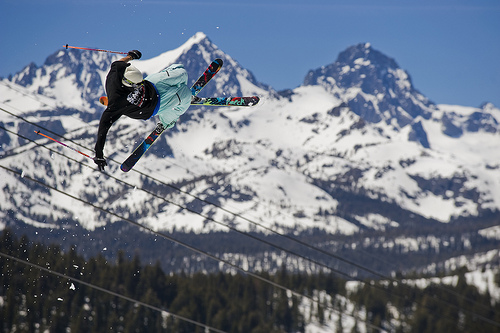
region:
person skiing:
[29, 28, 286, 188]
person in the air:
[13, 26, 291, 184]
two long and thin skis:
[116, 63, 265, 171]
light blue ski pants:
[149, 64, 198, 136]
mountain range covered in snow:
[1, 26, 499, 275]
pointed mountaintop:
[181, 22, 211, 52]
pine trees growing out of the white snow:
[1, 223, 496, 329]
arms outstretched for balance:
[27, 32, 144, 180]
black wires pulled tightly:
[0, 102, 496, 329]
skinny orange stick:
[28, 123, 105, 169]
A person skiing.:
[21, 35, 268, 215]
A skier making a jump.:
[23, 27, 274, 194]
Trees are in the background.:
[17, 242, 306, 330]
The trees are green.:
[35, 265, 259, 332]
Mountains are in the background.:
[281, 25, 477, 193]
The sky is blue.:
[427, 9, 494, 71]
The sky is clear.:
[419, 8, 497, 77]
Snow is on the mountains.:
[288, 20, 497, 187]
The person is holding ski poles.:
[20, 20, 277, 204]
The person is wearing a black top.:
[22, 26, 259, 206]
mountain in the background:
[80, 71, 340, 328]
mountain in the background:
[149, 50, 438, 275]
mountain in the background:
[111, 35, 381, 210]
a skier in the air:
[50, 21, 287, 192]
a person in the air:
[34, 6, 344, 201]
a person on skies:
[22, 17, 322, 228]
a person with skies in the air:
[59, 6, 348, 238]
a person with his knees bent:
[47, 14, 285, 155]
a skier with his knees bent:
[43, 24, 254, 179]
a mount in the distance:
[37, 7, 475, 309]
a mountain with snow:
[14, 27, 481, 327]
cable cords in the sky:
[10, 63, 331, 331]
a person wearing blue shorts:
[51, 13, 362, 188]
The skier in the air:
[90, 47, 189, 173]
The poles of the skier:
[27, 38, 138, 168]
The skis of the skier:
[98, 52, 262, 173]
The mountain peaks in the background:
[0, 28, 498, 141]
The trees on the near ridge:
[1, 228, 498, 331]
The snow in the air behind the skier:
[0, 166, 160, 313]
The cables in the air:
[0, 81, 496, 332]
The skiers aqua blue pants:
[144, 63, 194, 126]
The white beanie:
[120, 63, 146, 89]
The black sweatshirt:
[87, 56, 157, 153]